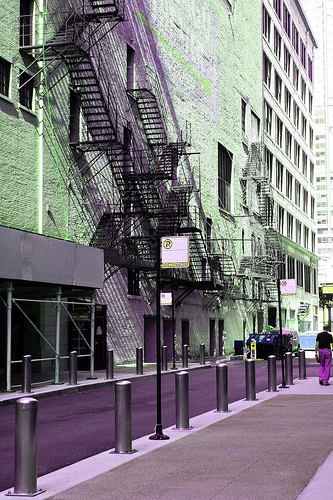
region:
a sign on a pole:
[137, 225, 202, 312]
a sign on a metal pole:
[137, 230, 224, 344]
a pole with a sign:
[145, 221, 233, 375]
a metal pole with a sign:
[125, 226, 242, 381]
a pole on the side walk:
[134, 229, 231, 485]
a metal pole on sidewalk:
[115, 213, 271, 497]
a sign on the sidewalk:
[144, 232, 227, 380]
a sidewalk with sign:
[127, 209, 232, 459]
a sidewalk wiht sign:
[119, 271, 233, 478]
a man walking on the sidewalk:
[309, 316, 328, 340]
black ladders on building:
[47, 22, 207, 292]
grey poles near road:
[111, 354, 278, 454]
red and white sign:
[140, 238, 188, 267]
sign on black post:
[151, 235, 168, 441]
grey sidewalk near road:
[125, 419, 304, 488]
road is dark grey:
[74, 381, 198, 446]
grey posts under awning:
[10, 297, 94, 389]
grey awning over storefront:
[6, 236, 123, 289]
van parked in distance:
[253, 304, 303, 362]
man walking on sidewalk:
[312, 321, 331, 389]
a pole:
[115, 380, 133, 457]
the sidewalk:
[211, 437, 275, 479]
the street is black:
[50, 403, 97, 438]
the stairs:
[122, 170, 170, 217]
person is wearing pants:
[318, 350, 332, 382]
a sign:
[161, 239, 188, 265]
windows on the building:
[272, 166, 306, 195]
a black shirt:
[317, 334, 328, 346]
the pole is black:
[152, 309, 167, 426]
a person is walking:
[313, 327, 332, 382]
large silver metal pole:
[298, 349, 306, 378]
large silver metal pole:
[285, 352, 293, 383]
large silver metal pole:
[268, 354, 277, 391]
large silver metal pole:
[244, 356, 258, 400]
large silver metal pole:
[214, 363, 230, 412]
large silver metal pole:
[173, 370, 191, 429]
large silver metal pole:
[113, 379, 133, 451]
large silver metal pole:
[14, 396, 40, 492]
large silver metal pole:
[20, 354, 31, 392]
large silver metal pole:
[68, 349, 78, 386]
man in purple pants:
[305, 324, 331, 390]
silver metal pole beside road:
[104, 378, 137, 459]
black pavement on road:
[45, 401, 103, 451]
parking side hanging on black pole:
[158, 231, 191, 271]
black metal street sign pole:
[147, 265, 169, 442]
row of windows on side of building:
[261, 44, 316, 183]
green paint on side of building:
[2, 123, 37, 211]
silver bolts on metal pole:
[4, 488, 36, 497]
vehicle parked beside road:
[266, 324, 302, 357]